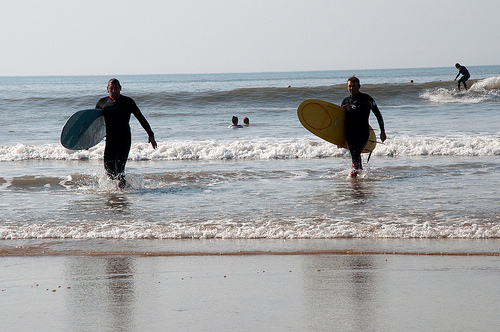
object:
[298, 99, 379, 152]
surfboard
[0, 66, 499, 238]
ocean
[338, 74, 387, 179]
man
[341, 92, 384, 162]
wetsuit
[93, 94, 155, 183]
wetsuit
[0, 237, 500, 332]
beach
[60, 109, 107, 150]
board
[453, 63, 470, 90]
surfer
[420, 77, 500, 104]
wave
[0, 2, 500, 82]
sky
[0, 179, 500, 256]
shore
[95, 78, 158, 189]
person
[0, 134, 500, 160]
wave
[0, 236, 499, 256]
shoreline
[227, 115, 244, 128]
people